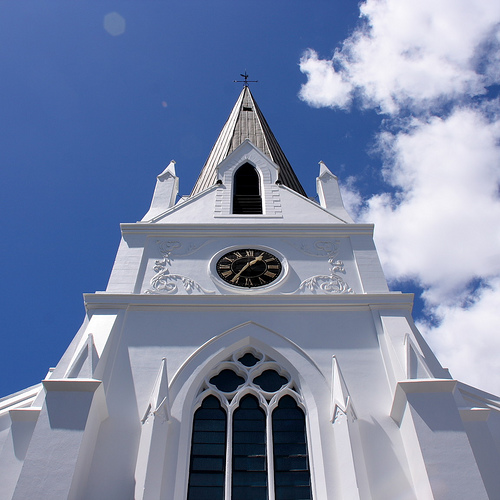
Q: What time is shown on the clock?
A: One thirty five.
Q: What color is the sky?
A: Blue.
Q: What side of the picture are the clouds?
A: Right.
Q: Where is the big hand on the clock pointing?
A: On the seven.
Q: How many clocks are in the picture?
A: One.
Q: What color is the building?
A: White.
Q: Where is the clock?
A: On the building.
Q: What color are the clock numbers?
A: Gold.